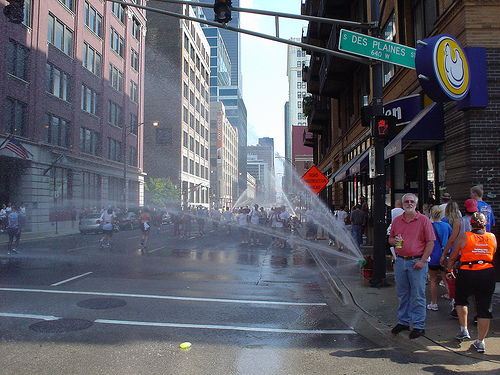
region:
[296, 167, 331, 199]
a orange and black construction sign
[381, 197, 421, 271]
a man holding a bottle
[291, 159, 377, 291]
a fire hydrant spraying water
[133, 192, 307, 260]
several people running in the street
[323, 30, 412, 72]
a green and white street sign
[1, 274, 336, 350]
white lines painted on a street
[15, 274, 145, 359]
two man hole covers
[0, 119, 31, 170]
a flag hanging on the side of a building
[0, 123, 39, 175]
a flag and flag pole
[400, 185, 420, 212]
a man wearing glasses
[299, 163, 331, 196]
A bright orange road construction sign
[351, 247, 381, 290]
A red fire hydrant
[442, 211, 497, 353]
A woman in a bright orange shirt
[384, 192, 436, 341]
A man in a pink shirt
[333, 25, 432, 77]
A green street sign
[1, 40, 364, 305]
Water spraying out of the hydrant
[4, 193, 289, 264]
Runners on the paved road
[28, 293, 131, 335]
Two manhole covers in the road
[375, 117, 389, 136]
A red don't walk signal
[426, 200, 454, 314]
A woman in a blue t shirt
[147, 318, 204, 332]
white line on the street.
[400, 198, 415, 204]
glasses on man's face.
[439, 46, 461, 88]
logo on the sign.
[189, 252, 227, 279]
water on the street.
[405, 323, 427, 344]
shoe on man's foot.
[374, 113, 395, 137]
traffic sign for pedestrians.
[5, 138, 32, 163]
flag on a pole.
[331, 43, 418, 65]
street sign above sidewalk.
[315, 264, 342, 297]
curb of the sidewalk.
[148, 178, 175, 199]
leaves on the tree.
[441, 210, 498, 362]
woman wearing orange shirt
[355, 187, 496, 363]
a man wearing pink shirt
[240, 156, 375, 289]
water coming out from hydratant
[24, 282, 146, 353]
two cover of drains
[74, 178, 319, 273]
people running on the road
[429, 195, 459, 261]
blonde woman with blue top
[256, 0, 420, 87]
a green sign over a pole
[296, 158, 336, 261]
an orange sign on side street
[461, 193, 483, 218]
a red cap on head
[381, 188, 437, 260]
man has gray hair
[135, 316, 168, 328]
white paint on street.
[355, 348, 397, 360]
shadow on the street.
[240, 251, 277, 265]
water in the street.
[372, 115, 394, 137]
sign for the pedestrians.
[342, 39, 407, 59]
street sign above sidewalk.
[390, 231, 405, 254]
bottle in man's hand.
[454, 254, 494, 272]
band on woman's waist.